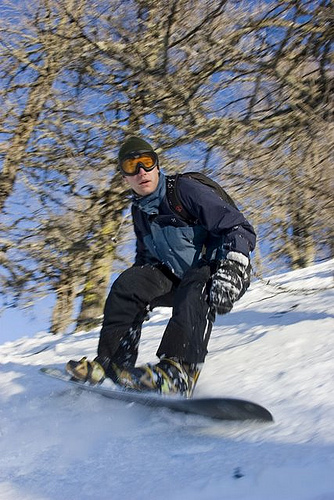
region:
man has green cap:
[103, 122, 155, 163]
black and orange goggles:
[127, 141, 159, 181]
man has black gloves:
[206, 257, 270, 309]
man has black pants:
[67, 264, 220, 382]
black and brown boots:
[62, 349, 187, 401]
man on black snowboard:
[29, 373, 250, 430]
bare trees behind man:
[28, 1, 313, 249]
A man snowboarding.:
[38, 135, 271, 423]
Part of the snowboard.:
[214, 394, 273, 421]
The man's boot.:
[119, 356, 197, 396]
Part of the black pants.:
[189, 325, 202, 349]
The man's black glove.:
[209, 259, 242, 314]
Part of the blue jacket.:
[175, 243, 196, 259]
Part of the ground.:
[69, 446, 100, 480]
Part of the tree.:
[63, 230, 82, 260]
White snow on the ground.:
[255, 320, 289, 351]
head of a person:
[118, 129, 173, 196]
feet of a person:
[69, 358, 136, 393]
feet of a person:
[121, 366, 207, 402]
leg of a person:
[86, 263, 171, 356]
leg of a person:
[161, 295, 241, 361]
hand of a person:
[191, 281, 248, 311]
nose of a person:
[135, 168, 146, 178]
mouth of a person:
[135, 179, 154, 188]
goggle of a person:
[122, 147, 158, 172]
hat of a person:
[119, 129, 163, 153]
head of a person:
[105, 128, 161, 194]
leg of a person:
[77, 244, 155, 353]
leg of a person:
[160, 286, 222, 363]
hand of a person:
[201, 275, 251, 315]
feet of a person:
[58, 342, 123, 391]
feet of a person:
[119, 366, 192, 397]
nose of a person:
[135, 168, 150, 178]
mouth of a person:
[139, 174, 150, 191]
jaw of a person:
[140, 183, 156, 194]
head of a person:
[108, 133, 165, 196]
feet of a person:
[64, 346, 124, 387]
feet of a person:
[124, 355, 183, 399]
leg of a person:
[97, 263, 150, 356]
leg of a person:
[164, 280, 217, 360]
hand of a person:
[197, 265, 251, 306]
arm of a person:
[211, 205, 261, 277]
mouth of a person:
[137, 178, 152, 187]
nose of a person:
[135, 160, 149, 179]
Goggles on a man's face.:
[115, 152, 159, 175]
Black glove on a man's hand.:
[211, 259, 249, 312]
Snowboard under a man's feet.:
[32, 357, 273, 428]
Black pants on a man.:
[95, 250, 224, 372]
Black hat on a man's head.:
[115, 130, 159, 158]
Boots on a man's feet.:
[64, 348, 208, 401]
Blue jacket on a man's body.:
[121, 170, 262, 283]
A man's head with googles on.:
[108, 136, 163, 195]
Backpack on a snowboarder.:
[158, 165, 246, 241]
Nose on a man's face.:
[135, 165, 150, 177]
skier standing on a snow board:
[65, 135, 256, 394]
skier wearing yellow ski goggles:
[56, 139, 256, 395]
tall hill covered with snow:
[0, 259, 333, 498]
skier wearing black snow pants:
[62, 137, 257, 392]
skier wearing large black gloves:
[65, 135, 256, 395]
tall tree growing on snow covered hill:
[36, 0, 135, 329]